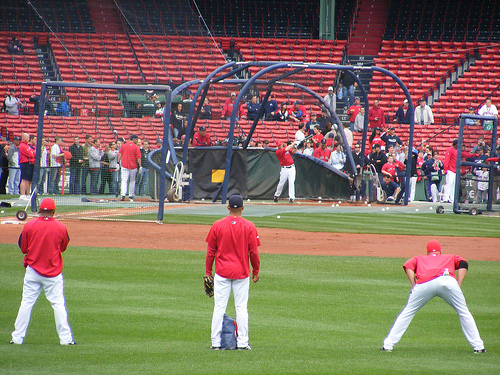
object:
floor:
[36, 45, 69, 109]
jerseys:
[441, 146, 481, 175]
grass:
[0, 194, 499, 375]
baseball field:
[0, 0, 499, 374]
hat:
[423, 238, 441, 254]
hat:
[37, 196, 59, 212]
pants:
[380, 273, 485, 351]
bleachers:
[0, 0, 499, 164]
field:
[0, 192, 498, 374]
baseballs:
[200, 196, 205, 203]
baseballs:
[198, 197, 208, 200]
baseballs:
[274, 215, 281, 220]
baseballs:
[314, 195, 322, 200]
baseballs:
[334, 200, 343, 205]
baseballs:
[412, 206, 418, 214]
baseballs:
[328, 204, 336, 209]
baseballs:
[332, 202, 341, 209]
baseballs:
[0, 208, 5, 216]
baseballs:
[361, 198, 369, 205]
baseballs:
[293, 198, 302, 204]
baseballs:
[427, 205, 434, 212]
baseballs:
[364, 202, 372, 209]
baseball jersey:
[400, 252, 470, 284]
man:
[8, 196, 80, 345]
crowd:
[0, 126, 152, 202]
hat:
[227, 192, 243, 207]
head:
[224, 196, 246, 214]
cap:
[128, 132, 139, 140]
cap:
[198, 126, 208, 131]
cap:
[319, 138, 327, 144]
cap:
[326, 131, 336, 140]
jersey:
[274, 144, 296, 168]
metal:
[28, 81, 173, 223]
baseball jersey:
[203, 215, 261, 279]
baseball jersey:
[18, 216, 71, 280]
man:
[201, 195, 261, 352]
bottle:
[442, 267, 451, 276]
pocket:
[439, 273, 453, 288]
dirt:
[0, 198, 496, 264]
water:
[441, 267, 449, 277]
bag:
[218, 311, 239, 351]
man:
[377, 236, 487, 354]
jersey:
[116, 142, 142, 171]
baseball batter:
[270, 138, 302, 204]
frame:
[145, 59, 415, 205]